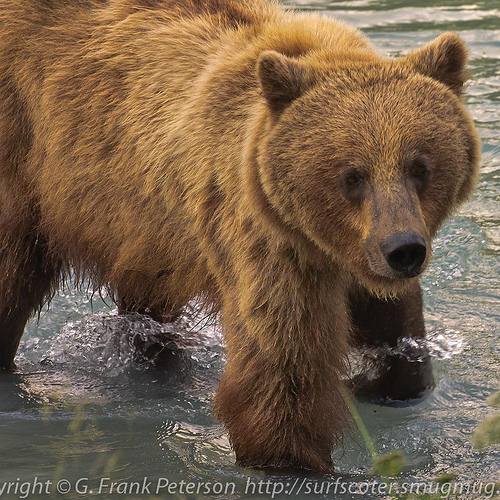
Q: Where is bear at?
A: Standing in water.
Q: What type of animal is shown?
A: Bear.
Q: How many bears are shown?
A: 1.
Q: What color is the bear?
A: Brown.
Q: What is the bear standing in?
A: Water.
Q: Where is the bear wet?
A: Feet and belly.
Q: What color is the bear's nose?
A: Black.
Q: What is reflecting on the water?
A: Sun.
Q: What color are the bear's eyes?
A: Black.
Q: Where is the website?
A: Bottom of the image.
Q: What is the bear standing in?
A: Water.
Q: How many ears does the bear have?
A: Two.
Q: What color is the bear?
A: Brown.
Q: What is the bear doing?
A: Looking towards the camera.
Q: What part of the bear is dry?
A: The top portion.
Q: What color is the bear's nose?
A: Black.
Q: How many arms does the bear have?
A: 2.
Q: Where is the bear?
A: In the water.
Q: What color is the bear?
A: Brown.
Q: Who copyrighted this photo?
A: G. Frank Peterson.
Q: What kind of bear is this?
A: Large brown bear.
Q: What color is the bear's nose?
A: Black.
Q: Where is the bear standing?
A: The water.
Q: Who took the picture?
A: Frank Peterson.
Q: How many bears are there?
A: One.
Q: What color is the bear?
A: Brown.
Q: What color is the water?
A: Grey.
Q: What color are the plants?
A: Green.